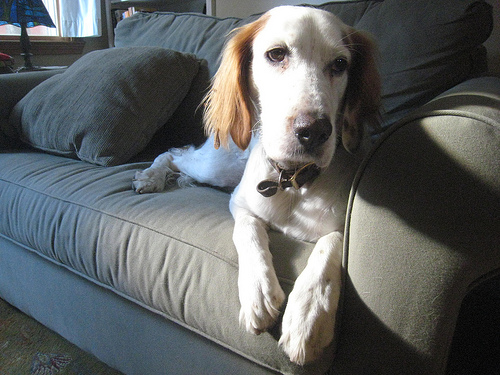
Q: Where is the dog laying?
A: On a couch.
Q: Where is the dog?
A: On the couch.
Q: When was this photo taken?
A: During daylight.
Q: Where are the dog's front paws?
A: Hanging over the edge of the cushion.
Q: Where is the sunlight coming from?
A: A window.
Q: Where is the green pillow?
A: Behind the dog.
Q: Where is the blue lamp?
A: In the background by the window.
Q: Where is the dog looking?
A: To the side of the camera.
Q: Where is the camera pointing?
A: Toward the dog on the sofa.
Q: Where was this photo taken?
A: In a living room.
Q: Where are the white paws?
A: On the dog.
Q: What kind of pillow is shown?
A: Gray.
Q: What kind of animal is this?
A: A dog.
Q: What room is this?
A: A living room.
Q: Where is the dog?
A: On the couch.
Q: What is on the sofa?
A: Pillows.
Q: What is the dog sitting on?
A: A Sofa.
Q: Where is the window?
A: Behind the lamp.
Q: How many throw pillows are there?
A: One.